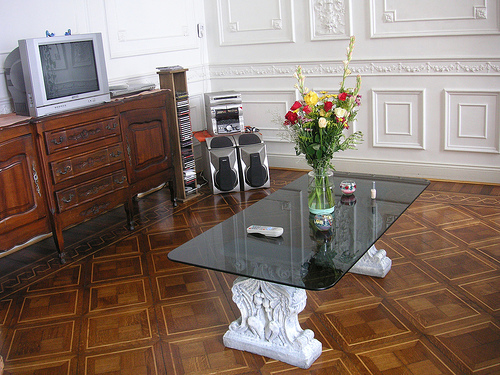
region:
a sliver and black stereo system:
[202, 86, 277, 195]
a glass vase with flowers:
[285, 27, 371, 233]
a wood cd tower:
[158, 61, 207, 206]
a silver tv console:
[0, 28, 112, 121]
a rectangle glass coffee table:
[164, 163, 431, 367]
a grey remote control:
[242, 219, 287, 240]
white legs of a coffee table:
[221, 197, 398, 369]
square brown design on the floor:
[1, 161, 497, 373]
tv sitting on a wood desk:
[0, 25, 187, 262]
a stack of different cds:
[174, 87, 200, 202]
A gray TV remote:
[244, 220, 284, 237]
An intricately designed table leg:
[223, 245, 315, 362]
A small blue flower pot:
[308, 199, 338, 231]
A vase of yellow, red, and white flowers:
[282, 85, 360, 228]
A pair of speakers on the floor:
[198, 131, 270, 187]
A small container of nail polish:
[363, 180, 377, 202]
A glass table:
[162, 161, 435, 306]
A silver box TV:
[5, 30, 119, 117]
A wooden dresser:
[0, 90, 186, 254]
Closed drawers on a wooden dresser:
[33, 117, 141, 204]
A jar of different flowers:
[263, 30, 366, 241]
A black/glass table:
[160, 162, 465, 367]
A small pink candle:
[335, 170, 360, 200]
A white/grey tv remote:
[225, 211, 291, 243]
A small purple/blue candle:
[301, 205, 341, 235]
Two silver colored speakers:
[195, 130, 277, 195]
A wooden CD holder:
[156, 60, 201, 205]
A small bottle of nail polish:
[362, 171, 377, 201]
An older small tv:
[0, 21, 125, 116]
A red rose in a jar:
[315, 93, 332, 115]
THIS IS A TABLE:
[150, 164, 438, 296]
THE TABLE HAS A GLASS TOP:
[153, 165, 438, 295]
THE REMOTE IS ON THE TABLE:
[240, 218, 290, 248]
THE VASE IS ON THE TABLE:
[297, 160, 340, 246]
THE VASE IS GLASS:
[303, 167, 350, 248]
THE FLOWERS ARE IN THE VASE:
[272, 85, 364, 200]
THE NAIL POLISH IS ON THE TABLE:
[364, 178, 385, 203]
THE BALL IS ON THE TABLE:
[336, 173, 360, 201]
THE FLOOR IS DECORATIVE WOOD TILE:
[6, 158, 498, 373]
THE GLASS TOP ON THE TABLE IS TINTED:
[164, 163, 437, 305]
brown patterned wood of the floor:
[70, 289, 179, 360]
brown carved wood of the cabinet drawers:
[57, 130, 122, 196]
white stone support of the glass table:
[212, 259, 332, 365]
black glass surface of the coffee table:
[214, 157, 407, 322]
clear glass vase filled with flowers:
[278, 84, 358, 239]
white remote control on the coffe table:
[243, 213, 294, 253]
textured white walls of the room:
[348, 23, 487, 136]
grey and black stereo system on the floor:
[193, 85, 279, 194]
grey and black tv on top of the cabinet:
[6, 16, 123, 118]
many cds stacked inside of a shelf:
[158, 70, 205, 192]